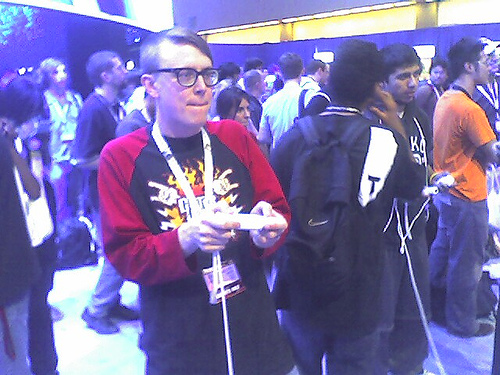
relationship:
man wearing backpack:
[269, 39, 425, 373] [270, 118, 435, 317]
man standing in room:
[68, 51, 139, 335] [3, 3, 491, 373]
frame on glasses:
[152, 65, 220, 87] [146, 66, 221, 87]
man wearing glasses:
[96, 26, 302, 372] [155, 63, 215, 93]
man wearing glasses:
[96, 26, 302, 372] [146, 66, 221, 87]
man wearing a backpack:
[269, 39, 425, 373] [264, 125, 371, 233]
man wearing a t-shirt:
[420, 35, 498, 324] [431, 85, 499, 201]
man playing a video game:
[96, 26, 302, 372] [193, 202, 305, 258]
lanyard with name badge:
[148, 118, 226, 262] [201, 261, 246, 305]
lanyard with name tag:
[148, 118, 226, 262] [196, 257, 248, 302]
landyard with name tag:
[475, 85, 495, 106] [483, 112, 497, 129]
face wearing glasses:
[169, 42, 222, 142] [173, 67, 220, 90]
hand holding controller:
[189, 202, 240, 252] [208, 212, 277, 230]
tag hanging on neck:
[207, 259, 250, 306] [146, 102, 204, 142]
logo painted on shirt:
[145, 180, 182, 225] [92, 115, 295, 373]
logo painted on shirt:
[145, 165, 243, 225] [92, 115, 295, 373]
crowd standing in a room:
[15, 24, 497, 350] [3, 3, 491, 373]